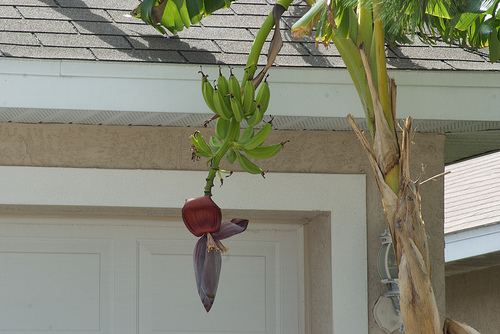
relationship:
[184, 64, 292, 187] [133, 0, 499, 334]
bananas on tree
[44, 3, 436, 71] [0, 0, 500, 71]
shadow on shadow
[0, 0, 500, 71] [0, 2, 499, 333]
shadow on building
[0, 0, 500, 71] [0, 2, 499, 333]
shadow of building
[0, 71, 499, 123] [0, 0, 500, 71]
portion below shadow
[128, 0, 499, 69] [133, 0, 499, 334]
leaves on tree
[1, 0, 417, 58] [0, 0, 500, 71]
tiles on shadow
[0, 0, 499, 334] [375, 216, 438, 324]
building has light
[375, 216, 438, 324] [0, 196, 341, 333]
light next to door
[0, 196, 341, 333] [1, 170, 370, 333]
door has trim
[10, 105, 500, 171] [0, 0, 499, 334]
soffit on building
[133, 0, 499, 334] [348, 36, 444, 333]
tree has bark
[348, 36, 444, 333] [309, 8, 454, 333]
bark on trunk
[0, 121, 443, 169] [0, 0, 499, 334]
wall on building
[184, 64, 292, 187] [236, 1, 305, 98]
bananas on stalk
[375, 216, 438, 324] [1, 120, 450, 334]
light on wall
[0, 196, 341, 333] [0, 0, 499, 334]
door of building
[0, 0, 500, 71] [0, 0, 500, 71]
shadow on shadow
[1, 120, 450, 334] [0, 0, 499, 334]
wall of building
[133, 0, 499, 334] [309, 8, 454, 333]
tree has trunk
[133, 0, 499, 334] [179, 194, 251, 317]
tree has flower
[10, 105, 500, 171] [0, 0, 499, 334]
soffit of building